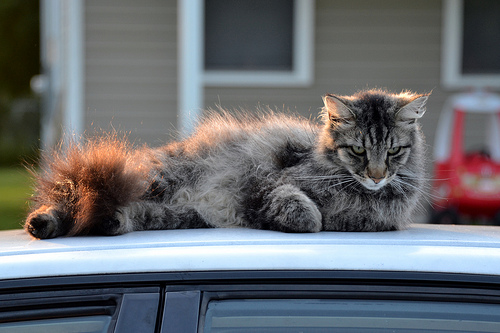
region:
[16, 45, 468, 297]
A cat is laying on a car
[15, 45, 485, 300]
A cat is tired from catching mice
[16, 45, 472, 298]
A cat is in front of somebody's house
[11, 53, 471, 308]
Cat on the roof of somebody's car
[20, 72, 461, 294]
The cat has long fur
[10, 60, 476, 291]
The cat is enjoying the summer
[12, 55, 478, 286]
The cat is looking for its master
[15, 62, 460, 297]
The cat is looking for its food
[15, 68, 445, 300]
The cat is waiting for a bird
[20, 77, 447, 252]
long hair cat on top of car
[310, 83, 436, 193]
cat staring at something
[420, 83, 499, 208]
red toy car in background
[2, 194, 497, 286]
roof of light blue car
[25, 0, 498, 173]
tan siding on house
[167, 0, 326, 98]
white window frame on house window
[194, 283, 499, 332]
black rubber window seal on car window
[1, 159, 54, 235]
green lawn in background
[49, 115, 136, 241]
long hair cat tail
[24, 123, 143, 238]
brown hair cat tail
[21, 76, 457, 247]
A grey and black cat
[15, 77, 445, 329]
The cat is on top of a car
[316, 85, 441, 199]
A cat with green eyes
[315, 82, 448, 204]
The cat is looking down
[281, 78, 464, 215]
A cat with long whiskers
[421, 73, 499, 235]
A red toy car in the background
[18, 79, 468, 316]
The cat is on a white car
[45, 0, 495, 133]
A beige house in the background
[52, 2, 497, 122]
The beige house has white trim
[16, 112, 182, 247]
The cat has a fluffy tail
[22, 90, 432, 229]
gray cat laying on a vehicle roof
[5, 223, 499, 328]
the roof of a vehicle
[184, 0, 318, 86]
window on a house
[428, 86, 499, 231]
red play car in the background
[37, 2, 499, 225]
gray and white house in the background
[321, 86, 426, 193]
the head of the gray cat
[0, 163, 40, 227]
grassy area next to the house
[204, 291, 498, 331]
window on the vehicle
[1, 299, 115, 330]
top portion of a window on the vehicle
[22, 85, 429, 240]
the tabby cat is laying on the car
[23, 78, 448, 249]
This is a cat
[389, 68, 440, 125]
Ear of a cat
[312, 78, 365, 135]
Ear of a cat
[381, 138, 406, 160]
Eye of a cat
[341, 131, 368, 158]
Eye of a cat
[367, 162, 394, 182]
Nose of a cat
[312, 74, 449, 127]
Ears of a cat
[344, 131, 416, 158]
Eyes of a cat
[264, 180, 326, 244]
Leg of a cat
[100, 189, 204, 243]
Leg of a cat